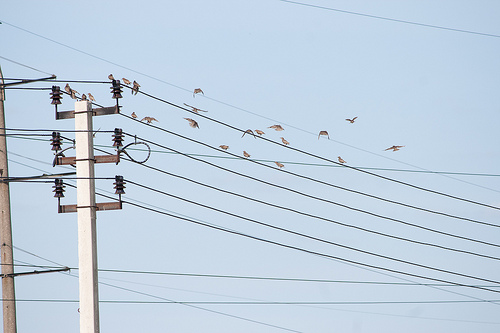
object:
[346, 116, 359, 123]
birds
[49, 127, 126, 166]
crossbar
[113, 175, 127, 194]
insulator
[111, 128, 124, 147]
insulator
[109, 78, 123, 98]
insulator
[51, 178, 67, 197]
insulator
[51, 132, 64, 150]
insulator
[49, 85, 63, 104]
insulator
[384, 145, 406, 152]
bird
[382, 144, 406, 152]
wing spread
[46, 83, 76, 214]
circuits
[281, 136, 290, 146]
bird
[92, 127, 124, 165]
bracket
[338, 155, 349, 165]
birds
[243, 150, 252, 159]
birds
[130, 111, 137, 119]
birds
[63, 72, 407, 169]
flock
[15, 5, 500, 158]
blue sky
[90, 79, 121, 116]
brackets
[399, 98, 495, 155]
white clouds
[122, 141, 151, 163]
looped cable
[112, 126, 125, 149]
inuslators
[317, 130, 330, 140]
bird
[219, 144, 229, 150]
bird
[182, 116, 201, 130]
bird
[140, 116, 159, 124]
bird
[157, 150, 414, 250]
telephone wire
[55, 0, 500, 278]
clouds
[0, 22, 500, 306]
cable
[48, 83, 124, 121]
crossbar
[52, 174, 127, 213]
crossbar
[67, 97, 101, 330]
pylon